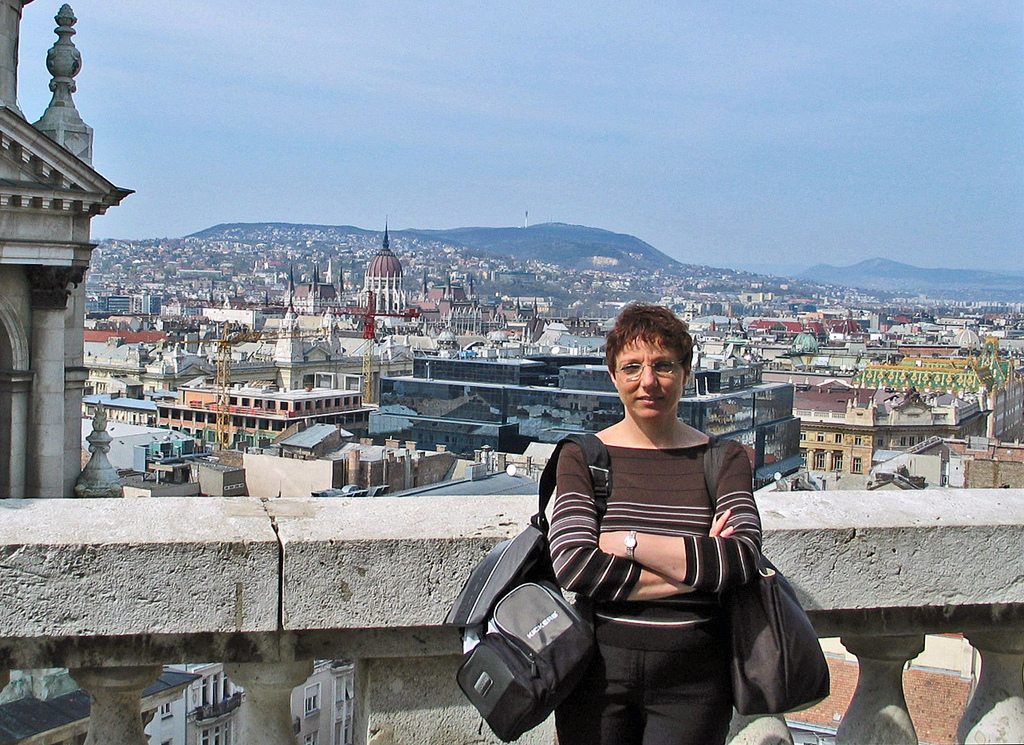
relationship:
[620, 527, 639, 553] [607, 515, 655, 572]
watch on wrist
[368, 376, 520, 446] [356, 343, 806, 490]
wall on side of building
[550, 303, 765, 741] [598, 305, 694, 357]
woman with brown hair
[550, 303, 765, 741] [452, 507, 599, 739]
woman carrying black bag